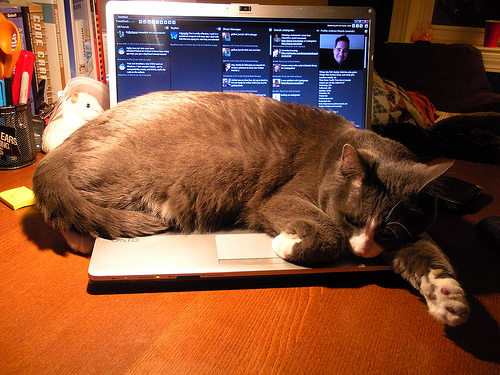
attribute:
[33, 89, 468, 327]
cat — dark, gray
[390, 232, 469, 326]
paw — white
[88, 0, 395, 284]
laptop — open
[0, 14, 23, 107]
scissor — orange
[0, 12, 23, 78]
handles — orange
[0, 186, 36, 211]
post-it notes — yellow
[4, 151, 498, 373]
wood — fake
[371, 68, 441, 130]
blanket — multi-colored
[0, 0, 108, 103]
books — lined up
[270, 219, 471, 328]
paws — white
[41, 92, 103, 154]
toy — mouse, white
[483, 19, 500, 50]
cup — red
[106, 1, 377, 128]
monitor — gray